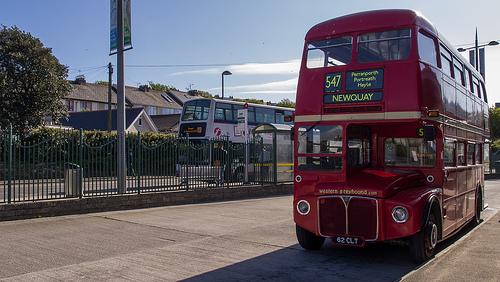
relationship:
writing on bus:
[323, 68, 379, 100] [288, 4, 493, 254]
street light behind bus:
[218, 67, 235, 95] [172, 87, 302, 186]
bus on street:
[301, 19, 492, 251] [13, 208, 303, 280]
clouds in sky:
[199, 51, 300, 100] [148, 7, 258, 52]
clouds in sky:
[171, 56, 298, 103] [4, 0, 296, 101]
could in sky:
[174, 58, 297, 103] [134, 4, 300, 102]